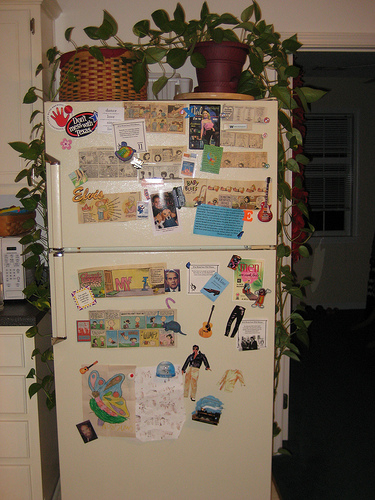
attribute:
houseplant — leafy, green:
[5, 1, 330, 465]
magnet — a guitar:
[256, 175, 276, 224]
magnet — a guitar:
[198, 303, 217, 341]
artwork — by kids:
[81, 364, 140, 442]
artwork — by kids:
[134, 362, 193, 444]